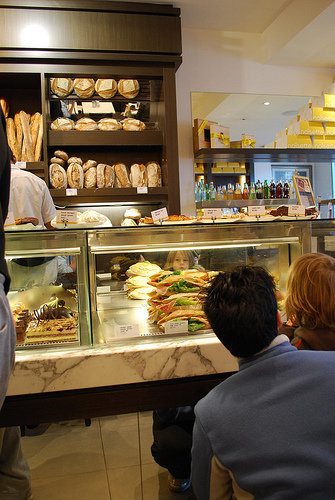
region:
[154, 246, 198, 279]
child's reflection in a mirror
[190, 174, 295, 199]
soda bottles lined up on a counter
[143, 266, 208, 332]
sandwiches stacked inside display case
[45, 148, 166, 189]
bread loaves on a display shelf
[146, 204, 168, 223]
display card on top of display case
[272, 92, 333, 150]
decorative bakery boxes on shelf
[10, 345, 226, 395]
marble slab in front of display case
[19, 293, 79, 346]
dessert displayed inside case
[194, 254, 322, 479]
back of a man's head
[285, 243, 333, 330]
back of child's head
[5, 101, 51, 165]
Tall loaves of bread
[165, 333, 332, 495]
A man in a light blue and white coat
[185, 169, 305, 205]
Various drinks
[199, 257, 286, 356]
The dark hair of a man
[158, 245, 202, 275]
A small child's face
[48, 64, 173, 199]
Various breads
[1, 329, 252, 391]
A large marbled counter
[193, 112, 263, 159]
Gift sets with bows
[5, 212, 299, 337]
Glass case with food inside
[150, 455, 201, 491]
Part of a mans shoe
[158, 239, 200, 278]
Child's reflection on display case.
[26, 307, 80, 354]
cake in display case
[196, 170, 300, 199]
Soda bottles on display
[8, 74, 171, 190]
Breads on display in brown case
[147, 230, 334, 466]
Adult squatting next to child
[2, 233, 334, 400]
Marble display case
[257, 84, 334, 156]
Yellow and white cake boxes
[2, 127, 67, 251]
Bakery clerk in white oxford shirt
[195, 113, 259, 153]
Yellow bows on pie boxes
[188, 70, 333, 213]
Mirror on wall.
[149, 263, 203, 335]
sandwiches in a deli case.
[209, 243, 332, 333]
man and child looking in deli tray.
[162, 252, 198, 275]
small child's reflection in a deli tray.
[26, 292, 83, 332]
chocolate dessert in a deli tray.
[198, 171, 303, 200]
soda bottles behind a counter.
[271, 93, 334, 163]
to go boxes on a ledge.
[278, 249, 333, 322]
a child with blonde hair.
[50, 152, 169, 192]
breads for sale in a bakery.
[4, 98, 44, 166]
baguettes for sale in a bakery.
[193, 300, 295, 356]
a man with dark black hair.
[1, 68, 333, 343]
Store with delicious food.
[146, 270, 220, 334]
Sandwiches in glass case.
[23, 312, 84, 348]
Cake in glass case.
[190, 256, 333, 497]
A man with small child.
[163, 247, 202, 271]
Reflection of small child.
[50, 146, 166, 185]
Baked bread on shelf.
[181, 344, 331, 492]
A man wearing blue shirt.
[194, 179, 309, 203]
Drinks on top of counter.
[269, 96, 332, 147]
Yellow boxes on top of shelf.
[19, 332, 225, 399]
Counter made with marble.